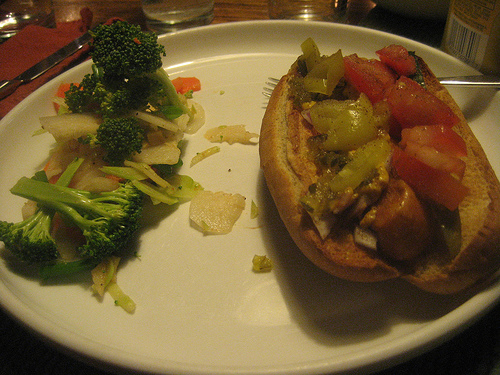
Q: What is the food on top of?
A: A white plate.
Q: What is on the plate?
A: Food is.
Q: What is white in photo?
A: The plate.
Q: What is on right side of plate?
A: A sandwich.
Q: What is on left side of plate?
A: Vegetables.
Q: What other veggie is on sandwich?
A: Onions.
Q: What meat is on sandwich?
A: Sausage.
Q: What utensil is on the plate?
A: A fork.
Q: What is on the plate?
A: Food.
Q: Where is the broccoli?
A: On the plate.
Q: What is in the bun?
A: Hot dog.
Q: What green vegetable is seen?
A: Broccoli.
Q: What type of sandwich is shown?
A: Hot dog.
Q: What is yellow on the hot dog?
A: Onions.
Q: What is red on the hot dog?
A: Tomatoes.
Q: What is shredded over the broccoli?
A: Parmesan cheese.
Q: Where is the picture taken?
A: A kitchen.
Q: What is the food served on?
A: A plate.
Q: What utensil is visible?
A: A knife.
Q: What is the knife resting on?
A: A napkin.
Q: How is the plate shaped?
A: Roundly.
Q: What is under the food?
A: A white round plate.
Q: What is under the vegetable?
A: A white plate.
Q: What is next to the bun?
A: A silver fork.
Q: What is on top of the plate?
A: Green broccoli.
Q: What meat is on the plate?
A: Hot dog.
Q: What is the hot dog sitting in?
A: A bun.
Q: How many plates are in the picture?
A: One.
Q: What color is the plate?
A: White.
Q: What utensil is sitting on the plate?
A: Fork.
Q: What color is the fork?
A: Silver.